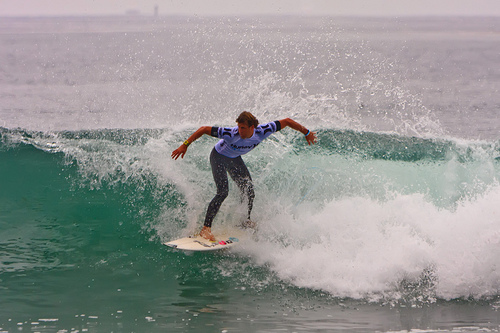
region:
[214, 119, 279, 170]
blue shirt worn by surfer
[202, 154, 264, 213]
black pants worn by person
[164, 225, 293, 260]
yellow surf board used by surfer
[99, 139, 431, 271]
frothy white wave under surfer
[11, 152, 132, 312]
greenish ocean water of wave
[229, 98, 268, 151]
man's short brown hair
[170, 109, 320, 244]
A surfer pretending to be a seagull.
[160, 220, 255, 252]
A surfboard being ridden.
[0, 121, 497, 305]
A breaking wave on a surfing beach.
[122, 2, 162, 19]
A ship and offshore platform.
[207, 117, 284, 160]
A polypropelene surfing shirt.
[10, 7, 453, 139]
Spray being thrown above a breaking wave.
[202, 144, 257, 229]
Poly-pro surfing trousers.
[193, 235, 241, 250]
Decals on a surfboard.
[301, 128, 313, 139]
A wristband being worn by a surfer.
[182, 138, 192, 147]
Sports watch and depth meter.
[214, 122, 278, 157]
The purple shirt the man is wearing.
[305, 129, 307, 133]
The blue bracelet on the man's wrist.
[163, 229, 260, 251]
The surfboard the man is riding.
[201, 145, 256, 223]
The pants the man is wearing.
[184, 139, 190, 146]
The yellow bracelet on the man's wrist.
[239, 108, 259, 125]
The man's short hair.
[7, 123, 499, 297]
The wave the man is riding.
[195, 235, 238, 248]
The design on the surfboard.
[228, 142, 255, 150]
The name on the front of the man's shirt.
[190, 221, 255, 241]
The feet of the man.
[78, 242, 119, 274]
white foam on water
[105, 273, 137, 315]
white foam on water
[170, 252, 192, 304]
white foam on water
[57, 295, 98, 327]
white foam on water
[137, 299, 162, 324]
white foam on water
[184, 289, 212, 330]
white foam on water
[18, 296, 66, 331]
white foam on water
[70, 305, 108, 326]
white foam on water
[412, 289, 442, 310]
white foam on water